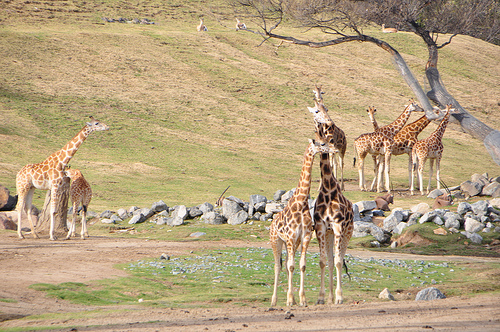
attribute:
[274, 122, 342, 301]
giraffes — standing, tallest, together, photographed, nine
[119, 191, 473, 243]
rocks — pile, small, line, row, large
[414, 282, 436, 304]
rock — single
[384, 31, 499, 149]
tree — large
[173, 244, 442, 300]
grass — trampled, sparse, green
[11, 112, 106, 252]
giraffe — adult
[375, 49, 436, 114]
branch — long, bare, no leaves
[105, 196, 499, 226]
wall — rock, natural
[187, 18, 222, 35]
animal — bovine, laying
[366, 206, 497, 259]
moss — green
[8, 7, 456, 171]
hill — sloping, large, brown, green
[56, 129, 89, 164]
neck — long, bending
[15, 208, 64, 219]
knees — knobby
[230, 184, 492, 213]
stones — pile, small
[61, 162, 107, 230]
giraffe — baby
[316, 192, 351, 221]
spots — giraffe